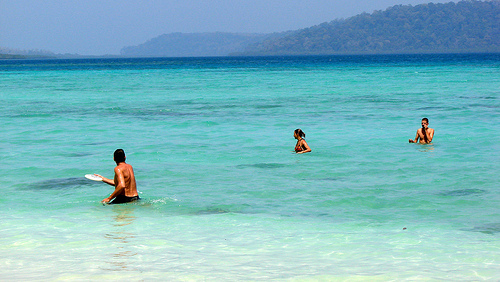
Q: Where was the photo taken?
A: At the ocean.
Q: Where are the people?
A: In the water.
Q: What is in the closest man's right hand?
A: A frisbee.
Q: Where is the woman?
A: In between the men.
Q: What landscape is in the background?
A: Mountains.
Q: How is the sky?
A: Hazy.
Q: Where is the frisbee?
A: In the man's right hand.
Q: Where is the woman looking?
A: To the left.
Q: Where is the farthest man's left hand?
A: Touching his face.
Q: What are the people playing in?
A: Turquoise water.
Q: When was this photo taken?
A: During the day.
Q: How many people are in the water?
A: Three.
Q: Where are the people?
A: In the ocean.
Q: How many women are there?
A: One.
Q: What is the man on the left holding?
A: A frisbee.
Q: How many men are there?
A: Two.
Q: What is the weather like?
A: Clear and sunny.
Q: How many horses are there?
A: Zero.